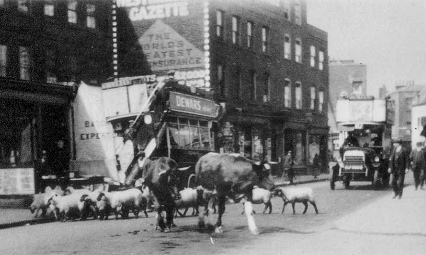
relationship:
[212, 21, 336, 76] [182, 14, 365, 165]
windows in building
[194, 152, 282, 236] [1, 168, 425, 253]
cow in street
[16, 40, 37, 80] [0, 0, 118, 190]
window on exterior of a building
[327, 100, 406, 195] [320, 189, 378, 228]
car in street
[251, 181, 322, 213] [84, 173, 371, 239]
animals crossing street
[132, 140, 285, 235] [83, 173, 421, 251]
cow crossing road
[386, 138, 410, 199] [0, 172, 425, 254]
man on road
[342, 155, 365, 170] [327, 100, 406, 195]
vent mounted on car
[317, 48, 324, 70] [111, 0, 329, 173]
window on top of building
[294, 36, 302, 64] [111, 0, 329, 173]
window on top of building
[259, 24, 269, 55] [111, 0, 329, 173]
window on top of building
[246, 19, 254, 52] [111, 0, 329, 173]
window on top of building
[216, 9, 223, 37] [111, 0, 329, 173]
window on top of building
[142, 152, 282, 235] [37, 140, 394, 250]
cow in street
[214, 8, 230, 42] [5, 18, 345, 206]
window on exterior of building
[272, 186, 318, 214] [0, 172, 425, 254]
animals on road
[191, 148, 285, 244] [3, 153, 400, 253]
cow in street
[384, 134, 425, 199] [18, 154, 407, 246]
people in street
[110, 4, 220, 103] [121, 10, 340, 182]
image on side of building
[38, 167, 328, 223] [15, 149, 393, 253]
sheep crossing road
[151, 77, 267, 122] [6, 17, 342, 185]
sign on building